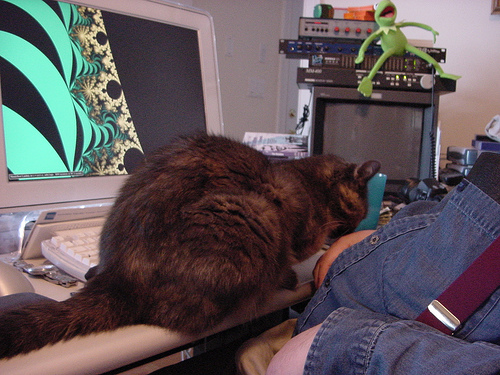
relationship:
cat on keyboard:
[1, 111, 408, 327] [39, 224, 114, 285]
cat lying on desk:
[0, 129, 385, 364] [1, 198, 468, 373]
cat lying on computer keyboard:
[0, 129, 385, 364] [40, 222, 105, 284]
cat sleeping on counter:
[0, 129, 385, 364] [13, 274, 320, 370]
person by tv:
[271, 152, 498, 374] [305, 86, 452, 207]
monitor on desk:
[1, 0, 255, 255] [1, 168, 433, 373]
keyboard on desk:
[39, 224, 104, 282] [2, 245, 327, 371]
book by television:
[241, 96, 351, 171] [118, 10, 319, 221]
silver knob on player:
[418, 73, 435, 89] [296, 67, 441, 92]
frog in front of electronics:
[355, 0, 455, 101] [271, 10, 461, 97]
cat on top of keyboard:
[0, 129, 385, 364] [37, 221, 105, 278]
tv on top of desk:
[305, 86, 442, 199] [2, 245, 327, 371]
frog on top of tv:
[351, 0, 455, 101] [315, 82, 446, 199]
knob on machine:
[333, 27, 341, 33] [296, 15, 378, 40]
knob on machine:
[344, 26, 351, 34] [296, 15, 378, 40]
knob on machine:
[356, 26, 362, 32] [296, 15, 378, 40]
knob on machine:
[366, 29, 372, 34] [296, 15, 378, 40]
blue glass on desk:
[353, 171, 388, 232] [4, 330, 239, 372]